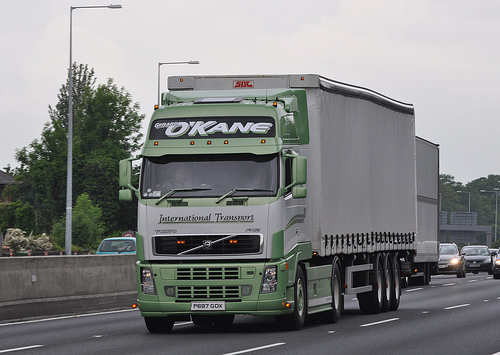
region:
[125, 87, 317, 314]
the truck's front is green and silver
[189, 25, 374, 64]
the sky is white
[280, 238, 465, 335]
the wheel's are black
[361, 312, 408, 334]
the line is white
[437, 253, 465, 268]
the headlights are on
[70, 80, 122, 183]
the tree is green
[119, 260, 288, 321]
the headlights are off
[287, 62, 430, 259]
the truck container is gray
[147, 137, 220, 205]
a man in the truck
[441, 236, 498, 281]
the cars are moving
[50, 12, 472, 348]
Picture of vehicles on highway.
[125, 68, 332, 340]
A green and white truck.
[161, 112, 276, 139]
The word OKANE in thire letters.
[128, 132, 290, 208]
Front windshield of truck.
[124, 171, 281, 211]
Windshield wipers on truck.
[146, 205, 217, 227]
The word International underlined.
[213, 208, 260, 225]
The word Transport underlined.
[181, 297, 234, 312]
White license tag with dark letters.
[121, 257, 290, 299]
Headlights on front of truck.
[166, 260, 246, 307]
Grill on front of truck.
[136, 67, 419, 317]
large semi-truck and trailer on highway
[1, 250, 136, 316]
jersey wall between lanes of opposite directions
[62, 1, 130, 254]
light pole on side of highway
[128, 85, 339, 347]
green cab of semi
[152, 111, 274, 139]
name of company owning truck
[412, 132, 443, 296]
portion of a second truck in lane beside first truck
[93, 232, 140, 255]
vehicle going in opposite direction from trucks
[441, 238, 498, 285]
cars following behind trucks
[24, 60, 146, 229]
tree in background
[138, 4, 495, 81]
overcast sky in background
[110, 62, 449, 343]
truck on a street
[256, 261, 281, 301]
front headlight on a vehicle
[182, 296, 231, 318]
front licence plate on a vehicle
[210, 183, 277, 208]
windshield wiper on a vehicle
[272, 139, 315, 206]
side rear view mirrors on a vehicle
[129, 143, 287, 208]
front windshield on a vehicle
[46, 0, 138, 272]
street light near a street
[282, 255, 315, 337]
front wheel of a vehicle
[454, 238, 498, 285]
car on a street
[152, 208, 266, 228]
company name on front of a vehicle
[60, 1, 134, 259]
Street light is in the background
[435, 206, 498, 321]
Sedans are behind truck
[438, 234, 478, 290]
Car has its headlights on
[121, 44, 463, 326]
Truck is light gray and green colored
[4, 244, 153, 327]
Truck is by a concrete divider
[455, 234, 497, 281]
Car in the background is black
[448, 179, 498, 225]
Street lights are in the background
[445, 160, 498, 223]
Trees are in the background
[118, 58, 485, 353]
Truck is on the road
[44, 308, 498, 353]
Highway is dark gray in color